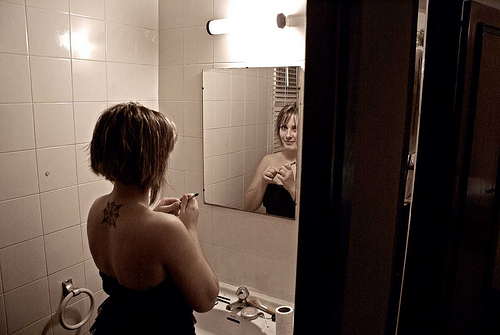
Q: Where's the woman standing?
A: Bathroom.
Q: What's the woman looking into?
A: Mirror.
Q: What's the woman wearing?
A: Dress.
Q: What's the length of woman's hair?
A: Short.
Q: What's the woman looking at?
A: Camera.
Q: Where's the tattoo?
A: On back.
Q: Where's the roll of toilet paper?
A: On sink.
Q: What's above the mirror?
A: Light.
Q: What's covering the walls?
A: Tile.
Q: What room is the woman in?
A: Bathroom.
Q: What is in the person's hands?
A: Make up.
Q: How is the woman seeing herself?
A: Mirror.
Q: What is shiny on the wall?
A: Tiles.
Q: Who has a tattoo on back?
A: Woman in mirror.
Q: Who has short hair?
A: Woman in black.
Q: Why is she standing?
A: Look at herself.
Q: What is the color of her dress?
A: Black.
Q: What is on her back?
A: A tattoo.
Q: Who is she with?
A: No one.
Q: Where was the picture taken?
A: In a bathroom.